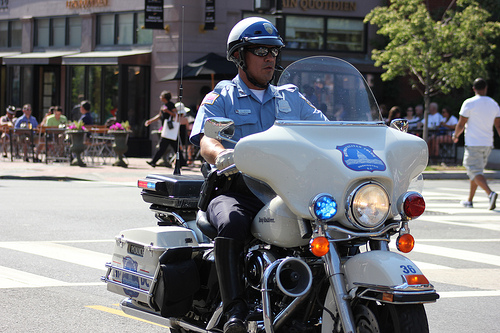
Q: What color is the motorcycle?
A: White.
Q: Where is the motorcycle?
A: On the road.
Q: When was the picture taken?
A: Daytime.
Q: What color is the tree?
A: Green.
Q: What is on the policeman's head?
A: A helmet.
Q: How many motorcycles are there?
A: One.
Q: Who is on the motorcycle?
A: A policeman.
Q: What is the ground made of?
A: Asphalt.